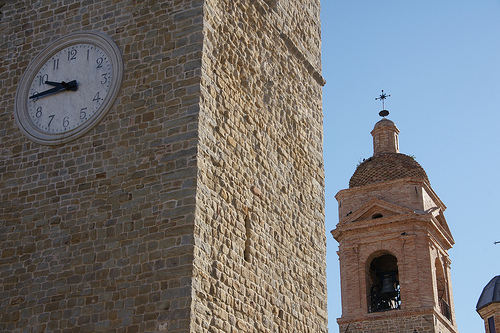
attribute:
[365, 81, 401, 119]
cross — metal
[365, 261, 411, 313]
metal bell — large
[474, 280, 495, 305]
roof — black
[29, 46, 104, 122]
face — white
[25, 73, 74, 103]
hands — black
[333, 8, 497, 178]
sky — blue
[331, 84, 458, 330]
building — pale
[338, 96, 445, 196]
top — round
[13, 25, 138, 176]
clock — dirty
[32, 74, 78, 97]
hand — black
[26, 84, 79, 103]
hand — black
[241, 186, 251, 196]
brick — irregular 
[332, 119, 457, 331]
tower — tan , colored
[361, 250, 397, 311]
opening — arched 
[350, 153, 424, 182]
roof — domed 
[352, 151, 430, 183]
roof — domed 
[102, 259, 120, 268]
bricks — Small 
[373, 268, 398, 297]
bell — black 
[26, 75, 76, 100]
hands — black 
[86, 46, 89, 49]
dots — Black 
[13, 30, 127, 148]
clock — round , stone 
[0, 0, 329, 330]
tower — stone 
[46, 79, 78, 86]
hour hand — Black 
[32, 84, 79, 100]
minute hand — Black 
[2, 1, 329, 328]
clock tower — stone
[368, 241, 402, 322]
window — arched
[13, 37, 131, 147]
clock face — white